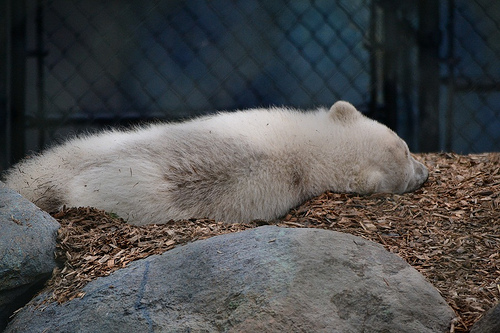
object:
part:
[215, 279, 238, 308]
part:
[366, 155, 387, 176]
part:
[432, 194, 446, 224]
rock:
[0, 225, 456, 333]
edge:
[128, 219, 412, 266]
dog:
[0, 89, 434, 230]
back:
[9, 109, 281, 224]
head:
[325, 101, 429, 196]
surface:
[396, 194, 498, 262]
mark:
[132, 261, 154, 333]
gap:
[49, 225, 61, 269]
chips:
[422, 221, 427, 228]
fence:
[0, 0, 500, 177]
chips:
[106, 260, 114, 269]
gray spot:
[165, 160, 238, 212]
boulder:
[0, 183, 63, 319]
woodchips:
[165, 239, 176, 246]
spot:
[329, 287, 391, 320]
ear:
[362, 170, 385, 196]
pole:
[11, 0, 46, 167]